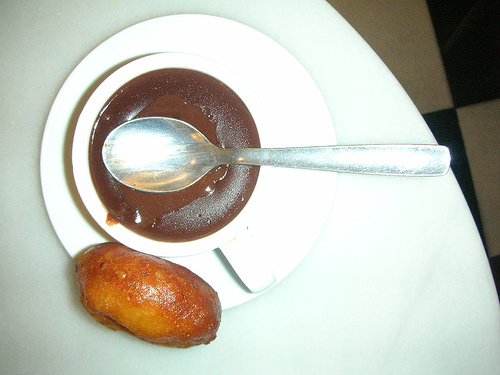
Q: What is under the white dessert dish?
A: Plate.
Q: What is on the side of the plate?
A: Bread.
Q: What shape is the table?
A: Round.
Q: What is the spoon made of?
A: Metal.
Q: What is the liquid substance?
A: Sauce.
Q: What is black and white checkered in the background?
A: Floor.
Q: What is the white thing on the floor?
A: Tile.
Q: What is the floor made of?
A: Tile.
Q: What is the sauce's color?
A: Brown.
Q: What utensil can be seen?
A: A spoon.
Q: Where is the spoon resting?
A: On pudding.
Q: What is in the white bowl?
A: Chocolate.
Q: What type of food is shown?
A: Desert.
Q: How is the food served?
A: On white plates.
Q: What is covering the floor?
A: Tile.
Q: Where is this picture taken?
A: A restaurant.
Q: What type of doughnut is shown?
A: Glazed.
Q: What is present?
A: Food.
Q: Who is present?
A: Nobody.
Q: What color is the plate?
A: White.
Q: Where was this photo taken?
A: In a restaurant.